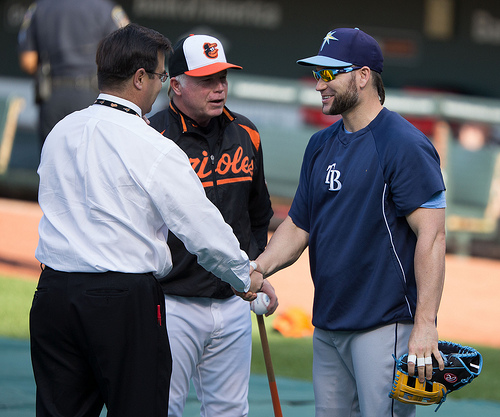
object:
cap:
[167, 34, 243, 76]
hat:
[294, 26, 384, 75]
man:
[29, 23, 281, 416]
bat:
[256, 313, 283, 416]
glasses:
[142, 64, 170, 84]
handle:
[256, 313, 269, 344]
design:
[320, 31, 340, 53]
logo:
[325, 162, 343, 192]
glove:
[388, 339, 483, 412]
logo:
[443, 372, 455, 384]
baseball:
[249, 291, 271, 315]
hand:
[257, 280, 279, 318]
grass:
[0, 272, 500, 405]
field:
[0, 196, 500, 416]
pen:
[155, 303, 161, 328]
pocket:
[84, 286, 126, 296]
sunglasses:
[310, 66, 360, 82]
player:
[233, 26, 446, 416]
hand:
[232, 260, 267, 302]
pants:
[28, 262, 173, 416]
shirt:
[287, 107, 445, 333]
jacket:
[146, 100, 274, 300]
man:
[147, 33, 274, 416]